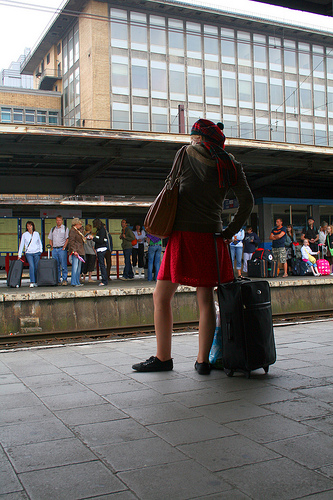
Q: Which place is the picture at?
A: It is at the sidewalk.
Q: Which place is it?
A: It is a sidewalk.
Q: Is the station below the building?
A: Yes, the station is below the building.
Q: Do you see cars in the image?
A: No, there are no cars.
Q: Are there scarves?
A: Yes, there is a scarf.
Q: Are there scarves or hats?
A: Yes, there is a scarf.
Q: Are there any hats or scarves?
A: Yes, there is a scarf.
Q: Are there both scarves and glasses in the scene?
A: No, there is a scarf but no glasses.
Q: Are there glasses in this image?
A: No, there are no glasses.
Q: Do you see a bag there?
A: Yes, there is a bag.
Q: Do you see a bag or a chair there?
A: Yes, there is a bag.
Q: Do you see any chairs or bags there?
A: Yes, there is a bag.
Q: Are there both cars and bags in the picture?
A: No, there is a bag but no cars.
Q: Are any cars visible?
A: No, there are no cars.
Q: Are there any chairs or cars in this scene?
A: No, there are no cars or chairs.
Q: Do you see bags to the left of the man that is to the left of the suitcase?
A: Yes, there is a bag to the left of the man.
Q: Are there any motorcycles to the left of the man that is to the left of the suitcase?
A: No, there is a bag to the left of the man.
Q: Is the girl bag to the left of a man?
A: Yes, the bag is to the left of a man.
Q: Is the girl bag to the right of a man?
A: No, the bag is to the left of a man.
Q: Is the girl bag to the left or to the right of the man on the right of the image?
A: The bag is to the left of the man.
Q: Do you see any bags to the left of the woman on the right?
A: Yes, there is a bag to the left of the woman.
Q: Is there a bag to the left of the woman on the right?
A: Yes, there is a bag to the left of the woman.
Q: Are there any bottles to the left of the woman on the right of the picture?
A: No, there is a bag to the left of the woman.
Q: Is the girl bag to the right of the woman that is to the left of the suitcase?
A: No, the bag is to the left of the woman.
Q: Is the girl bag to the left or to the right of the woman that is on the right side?
A: The bag is to the left of the woman.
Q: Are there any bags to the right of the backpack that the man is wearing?
A: Yes, there is a bag to the right of the backpack.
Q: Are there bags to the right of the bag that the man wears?
A: Yes, there is a bag to the right of the backpack.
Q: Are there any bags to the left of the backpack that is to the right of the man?
A: No, the bag is to the right of the backpack.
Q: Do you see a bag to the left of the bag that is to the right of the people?
A: No, the bag is to the right of the backpack.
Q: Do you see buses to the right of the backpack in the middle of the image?
A: No, there is a bag to the right of the backpack.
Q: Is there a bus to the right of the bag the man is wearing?
A: No, there is a bag to the right of the backpack.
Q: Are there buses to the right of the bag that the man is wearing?
A: No, there is a bag to the right of the backpack.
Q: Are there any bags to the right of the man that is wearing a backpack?
A: Yes, there is a bag to the right of the man.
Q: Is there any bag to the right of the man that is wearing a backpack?
A: Yes, there is a bag to the right of the man.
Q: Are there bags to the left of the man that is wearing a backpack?
A: No, the bag is to the right of the man.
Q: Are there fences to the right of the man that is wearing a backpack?
A: No, there is a bag to the right of the man.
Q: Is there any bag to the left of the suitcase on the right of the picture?
A: Yes, there is a bag to the left of the suitcase.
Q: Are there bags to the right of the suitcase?
A: No, the bag is to the left of the suitcase.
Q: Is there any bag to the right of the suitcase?
A: No, the bag is to the left of the suitcase.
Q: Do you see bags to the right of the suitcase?
A: No, the bag is to the left of the suitcase.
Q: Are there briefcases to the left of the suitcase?
A: No, there is a bag to the left of the suitcase.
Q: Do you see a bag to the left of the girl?
A: Yes, there is a bag to the left of the girl.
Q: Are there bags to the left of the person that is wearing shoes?
A: Yes, there is a bag to the left of the girl.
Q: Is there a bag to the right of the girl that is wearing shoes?
A: No, the bag is to the left of the girl.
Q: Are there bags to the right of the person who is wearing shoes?
A: No, the bag is to the left of the girl.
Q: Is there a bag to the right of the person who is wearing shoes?
A: No, the bag is to the left of the girl.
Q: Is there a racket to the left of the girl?
A: No, there is a bag to the left of the girl.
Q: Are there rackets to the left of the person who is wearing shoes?
A: No, there is a bag to the left of the girl.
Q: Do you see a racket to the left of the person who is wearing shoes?
A: No, there is a bag to the left of the girl.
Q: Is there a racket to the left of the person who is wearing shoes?
A: No, there is a bag to the left of the girl.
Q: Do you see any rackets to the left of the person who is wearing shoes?
A: No, there is a bag to the left of the girl.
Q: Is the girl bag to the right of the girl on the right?
A: No, the bag is to the left of the girl.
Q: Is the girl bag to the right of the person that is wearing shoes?
A: No, the bag is to the left of the girl.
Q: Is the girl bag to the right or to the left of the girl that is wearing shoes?
A: The bag is to the left of the girl.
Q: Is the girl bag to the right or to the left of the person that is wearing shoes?
A: The bag is to the left of the girl.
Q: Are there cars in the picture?
A: No, there are no cars.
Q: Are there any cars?
A: No, there are no cars.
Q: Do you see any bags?
A: Yes, there is a bag.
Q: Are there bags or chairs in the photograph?
A: Yes, there is a bag.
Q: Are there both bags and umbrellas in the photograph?
A: No, there is a bag but no umbrellas.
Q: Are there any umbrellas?
A: No, there are no umbrellas.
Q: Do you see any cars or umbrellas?
A: No, there are no umbrellas or cars.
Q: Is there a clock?
A: No, there are no clocks.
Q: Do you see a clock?
A: No, there are no clocks.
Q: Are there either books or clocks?
A: No, there are no clocks or books.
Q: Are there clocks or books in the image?
A: No, there are no clocks or books.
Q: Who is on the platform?
A: The people are on the platform.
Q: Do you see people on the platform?
A: Yes, there are people on the platform.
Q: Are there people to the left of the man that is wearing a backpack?
A: Yes, there are people to the left of the man.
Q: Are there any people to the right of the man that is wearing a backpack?
A: No, the people are to the left of the man.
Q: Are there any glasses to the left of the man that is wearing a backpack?
A: No, there are people to the left of the man.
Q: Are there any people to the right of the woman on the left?
A: Yes, there are people to the right of the woman.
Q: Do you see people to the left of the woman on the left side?
A: No, the people are to the right of the woman.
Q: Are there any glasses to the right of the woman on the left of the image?
A: No, there are people to the right of the woman.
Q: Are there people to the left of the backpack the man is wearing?
A: Yes, there are people to the left of the backpack.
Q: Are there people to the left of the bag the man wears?
A: Yes, there are people to the left of the backpack.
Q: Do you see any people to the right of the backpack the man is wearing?
A: No, the people are to the left of the backpack.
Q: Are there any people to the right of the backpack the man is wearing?
A: No, the people are to the left of the backpack.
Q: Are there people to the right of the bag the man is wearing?
A: No, the people are to the left of the backpack.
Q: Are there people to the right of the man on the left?
A: Yes, there are people to the right of the man.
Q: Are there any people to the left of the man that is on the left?
A: No, the people are to the right of the man.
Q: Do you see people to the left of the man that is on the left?
A: No, the people are to the right of the man.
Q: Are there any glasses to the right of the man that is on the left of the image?
A: No, there are people to the right of the man.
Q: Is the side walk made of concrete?
A: Yes, the side walk is made of concrete.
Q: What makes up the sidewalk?
A: The sidewalk is made of cement.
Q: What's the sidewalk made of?
A: The sidewalk is made of concrete.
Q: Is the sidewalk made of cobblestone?
A: No, the sidewalk is made of concrete.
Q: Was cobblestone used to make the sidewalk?
A: No, the sidewalk is made of concrete.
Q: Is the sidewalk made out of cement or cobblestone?
A: The sidewalk is made of cement.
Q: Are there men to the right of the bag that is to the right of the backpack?
A: Yes, there is a man to the right of the bag.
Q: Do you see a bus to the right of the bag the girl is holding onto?
A: No, there is a man to the right of the bag.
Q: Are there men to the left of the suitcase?
A: Yes, there is a man to the left of the suitcase.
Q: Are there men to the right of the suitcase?
A: No, the man is to the left of the suitcase.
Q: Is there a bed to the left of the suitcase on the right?
A: No, there is a man to the left of the suitcase.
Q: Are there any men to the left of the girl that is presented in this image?
A: Yes, there is a man to the left of the girl.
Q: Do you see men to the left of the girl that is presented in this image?
A: Yes, there is a man to the left of the girl.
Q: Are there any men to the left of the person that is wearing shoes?
A: Yes, there is a man to the left of the girl.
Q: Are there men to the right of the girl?
A: No, the man is to the left of the girl.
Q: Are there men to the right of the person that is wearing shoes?
A: No, the man is to the left of the girl.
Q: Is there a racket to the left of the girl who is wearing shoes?
A: No, there is a man to the left of the girl.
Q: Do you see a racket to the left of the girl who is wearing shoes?
A: No, there is a man to the left of the girl.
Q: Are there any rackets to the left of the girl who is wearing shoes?
A: No, there is a man to the left of the girl.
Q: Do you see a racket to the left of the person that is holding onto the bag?
A: No, there is a man to the left of the girl.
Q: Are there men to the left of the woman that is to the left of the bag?
A: Yes, there is a man to the left of the woman.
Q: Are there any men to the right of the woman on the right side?
A: No, the man is to the left of the woman.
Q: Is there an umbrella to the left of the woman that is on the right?
A: No, there is a man to the left of the woman.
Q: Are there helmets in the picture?
A: No, there are no helmets.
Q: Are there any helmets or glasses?
A: No, there are no helmets or glasses.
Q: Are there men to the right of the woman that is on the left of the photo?
A: Yes, there is a man to the right of the woman.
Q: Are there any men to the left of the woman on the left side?
A: No, the man is to the right of the woman.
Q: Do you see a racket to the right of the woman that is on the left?
A: No, there is a man to the right of the woman.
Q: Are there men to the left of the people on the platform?
A: Yes, there is a man to the left of the people.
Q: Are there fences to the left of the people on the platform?
A: No, there is a man to the left of the people.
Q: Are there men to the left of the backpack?
A: Yes, there is a man to the left of the backpack.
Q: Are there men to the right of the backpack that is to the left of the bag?
A: No, the man is to the left of the backpack.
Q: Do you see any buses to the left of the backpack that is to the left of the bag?
A: No, there is a man to the left of the backpack.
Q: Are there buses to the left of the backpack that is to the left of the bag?
A: No, there is a man to the left of the backpack.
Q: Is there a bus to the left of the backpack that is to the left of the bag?
A: No, there is a man to the left of the backpack.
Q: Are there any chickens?
A: No, there are no chickens.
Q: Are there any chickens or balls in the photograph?
A: No, there are no chickens or balls.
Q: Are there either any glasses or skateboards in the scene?
A: No, there are no glasses or skateboards.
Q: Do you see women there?
A: Yes, there is a woman.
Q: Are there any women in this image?
A: Yes, there is a woman.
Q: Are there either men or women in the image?
A: Yes, there is a woman.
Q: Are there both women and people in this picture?
A: Yes, there are both a woman and a person.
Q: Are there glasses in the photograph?
A: No, there are no glasses.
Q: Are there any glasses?
A: No, there are no glasses.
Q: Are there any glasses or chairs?
A: No, there are no glasses or chairs.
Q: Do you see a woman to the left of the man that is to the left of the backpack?
A: Yes, there is a woman to the left of the man.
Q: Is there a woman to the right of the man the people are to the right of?
A: No, the woman is to the left of the man.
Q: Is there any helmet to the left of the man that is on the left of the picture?
A: No, there is a woman to the left of the man.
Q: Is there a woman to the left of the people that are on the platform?
A: Yes, there is a woman to the left of the people.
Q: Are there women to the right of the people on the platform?
A: No, the woman is to the left of the people.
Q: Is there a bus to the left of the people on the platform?
A: No, there is a woman to the left of the people.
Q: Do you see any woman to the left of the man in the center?
A: Yes, there is a woman to the left of the man.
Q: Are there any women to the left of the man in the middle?
A: Yes, there is a woman to the left of the man.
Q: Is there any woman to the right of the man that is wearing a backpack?
A: No, the woman is to the left of the man.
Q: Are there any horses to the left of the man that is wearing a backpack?
A: No, there is a woman to the left of the man.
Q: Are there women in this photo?
A: Yes, there is a woman.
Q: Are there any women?
A: Yes, there is a woman.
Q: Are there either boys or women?
A: Yes, there is a woman.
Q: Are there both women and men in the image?
A: Yes, there are both a woman and a man.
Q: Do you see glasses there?
A: No, there are no glasses.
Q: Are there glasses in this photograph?
A: No, there are no glasses.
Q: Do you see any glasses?
A: No, there are no glasses.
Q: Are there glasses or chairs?
A: No, there are no glasses or chairs.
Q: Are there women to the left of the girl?
A: Yes, there is a woman to the left of the girl.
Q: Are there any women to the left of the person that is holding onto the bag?
A: Yes, there is a woman to the left of the girl.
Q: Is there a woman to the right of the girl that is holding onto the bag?
A: No, the woman is to the left of the girl.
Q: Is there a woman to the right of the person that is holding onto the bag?
A: No, the woman is to the left of the girl.